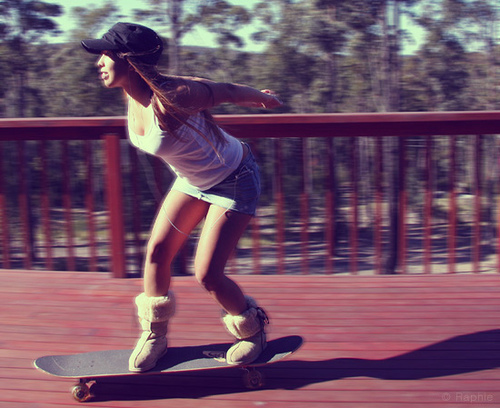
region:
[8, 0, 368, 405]
girl riding grey skateboard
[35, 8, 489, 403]
girl casting long shadow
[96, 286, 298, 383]
girl wearing tan boots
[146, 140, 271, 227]
girl wearing blue jean skirt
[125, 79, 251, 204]
woman wearing white shirt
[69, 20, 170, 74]
woman wearing black hat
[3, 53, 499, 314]
red railing behind woman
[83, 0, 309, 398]
woman has arm extended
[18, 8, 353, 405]
woman has knees slightly bent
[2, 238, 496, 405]
floor is red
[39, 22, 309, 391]
girl on a black longboard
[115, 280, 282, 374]
girl wearing furry boots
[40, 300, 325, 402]
black longboard with clear wheels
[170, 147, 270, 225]
mini jeans skirt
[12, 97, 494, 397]
brown deck with brown wood fence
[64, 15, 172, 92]
black hat on girl's head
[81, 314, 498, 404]
shadow on wooden deck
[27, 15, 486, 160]
row of green trees in the background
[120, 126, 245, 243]
white wire on earrphones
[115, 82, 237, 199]
girl wearing a plain white tank top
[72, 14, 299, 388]
A girl skateboarding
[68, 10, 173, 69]
A black baseball hat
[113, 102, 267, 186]
A white tank top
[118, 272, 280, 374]
Light brown boot with fur trim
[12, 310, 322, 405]
A black skateboard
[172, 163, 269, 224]
A blue jean skirt or shorts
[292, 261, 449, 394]
A brown wooden floor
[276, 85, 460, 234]
A brown fence railing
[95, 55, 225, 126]
A girl with red hair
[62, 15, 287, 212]
A girl with arms out behind her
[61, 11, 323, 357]
a girl rides a skate board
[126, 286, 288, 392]
the boots are furry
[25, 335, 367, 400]
a skate board on the deck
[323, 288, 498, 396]
a red wood deck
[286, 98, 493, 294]
the rail on the deck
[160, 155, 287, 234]
the girl in a mini skirt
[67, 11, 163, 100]
the girl wears a black cap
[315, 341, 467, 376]
a shadow cast behind her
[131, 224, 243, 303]
the girl has bare knees no pads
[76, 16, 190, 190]
she leans forward on the board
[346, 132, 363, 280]
wooden post on porch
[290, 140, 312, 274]
wooden post on porch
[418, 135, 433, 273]
wooden post on porch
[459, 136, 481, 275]
wooden post on porch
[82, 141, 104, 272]
wooden post on porch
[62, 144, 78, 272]
wooden post on porch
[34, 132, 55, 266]
wooden post on porch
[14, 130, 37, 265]
wooden post on porch